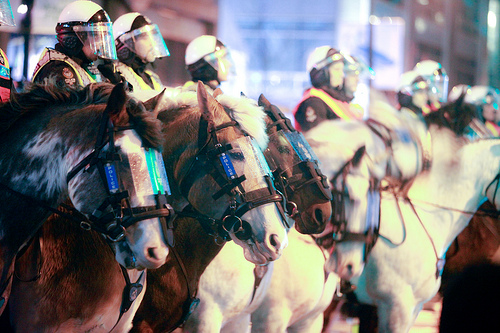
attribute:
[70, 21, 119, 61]
face mask — protective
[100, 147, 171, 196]
shield — protective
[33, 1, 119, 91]
policeman — mounted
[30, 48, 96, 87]
vest — yellow, red, orange, bullet proof, reflective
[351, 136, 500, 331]
horse — large, white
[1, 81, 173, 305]
horse — brown, white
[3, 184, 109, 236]
reigns — leather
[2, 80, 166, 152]
mane — brown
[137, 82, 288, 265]
horse — brown, palomino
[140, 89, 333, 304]
horse — brown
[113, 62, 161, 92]
vest — yellow, red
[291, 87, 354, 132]
vest — yellow, red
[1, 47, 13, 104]
vest — yellow, red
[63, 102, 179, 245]
bridle — black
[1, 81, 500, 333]
horses — lined up, in a row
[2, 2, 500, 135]
buildings — background